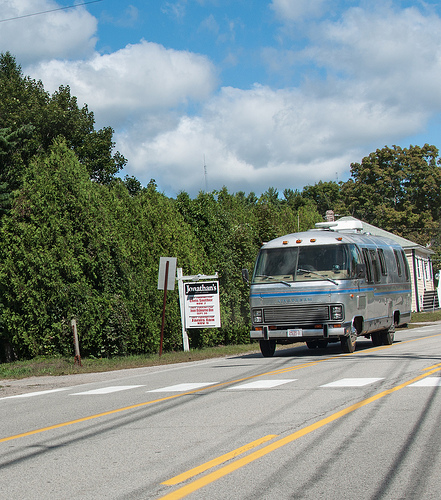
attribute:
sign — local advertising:
[180, 277, 224, 347]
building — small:
[407, 213, 435, 311]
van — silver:
[247, 228, 414, 352]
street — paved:
[0, 320, 440, 498]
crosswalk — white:
[0, 375, 440, 400]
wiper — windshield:
[294, 263, 339, 287]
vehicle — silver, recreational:
[246, 228, 412, 355]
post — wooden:
[159, 270, 171, 350]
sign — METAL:
[178, 267, 234, 341]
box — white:
[322, 375, 385, 388]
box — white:
[238, 371, 293, 391]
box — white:
[156, 374, 215, 393]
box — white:
[78, 379, 140, 398]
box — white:
[5, 391, 61, 397]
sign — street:
[156, 255, 176, 290]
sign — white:
[178, 277, 222, 331]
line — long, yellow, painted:
[158, 368, 437, 497]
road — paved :
[128, 344, 298, 495]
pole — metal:
[69, 314, 83, 363]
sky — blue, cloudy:
[2, 0, 439, 197]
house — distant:
[365, 219, 427, 321]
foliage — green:
[3, 48, 439, 351]